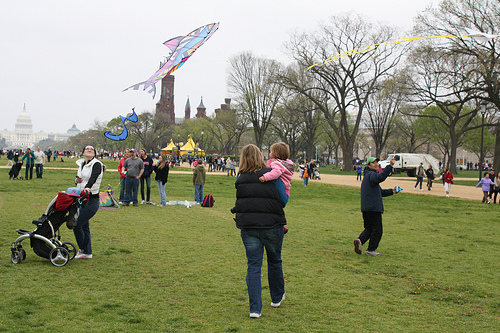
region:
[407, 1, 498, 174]
a bare tree in the park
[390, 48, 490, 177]
a bare tree in the park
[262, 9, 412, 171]
a bare tree in the park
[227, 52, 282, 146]
a bare tree in the park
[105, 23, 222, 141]
a colorful kite flying in the air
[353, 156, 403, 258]
a man wearing a dark blue jacket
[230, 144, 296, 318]
a woman wearing a black vest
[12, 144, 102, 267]
a woman wearing a white vest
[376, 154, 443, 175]
a white garbage truck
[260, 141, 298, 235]
a baby wearing a pink jacket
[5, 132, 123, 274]
a woman pushing a stroller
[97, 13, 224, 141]
a kite shaped like a fish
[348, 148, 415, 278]
a man flying a kite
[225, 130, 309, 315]
a woman carrying a baby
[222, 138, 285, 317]
a woman in ab lack coat and blue jeans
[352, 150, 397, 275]
a man in a green cap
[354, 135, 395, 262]
a man in a blue coat and black pants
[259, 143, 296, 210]
a child in a pink coat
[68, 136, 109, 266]
a woman in a white vest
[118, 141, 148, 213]
a man in a grey sweater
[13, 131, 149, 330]
a woman pushing a stroller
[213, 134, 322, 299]
a woman holding a little girl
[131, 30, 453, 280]
a man flying a kite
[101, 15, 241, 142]
a shark shaped kite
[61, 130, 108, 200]
a woman wearing a white vest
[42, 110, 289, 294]
people standing on grass in a field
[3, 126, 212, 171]
people standing on the grass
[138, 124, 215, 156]
two yellow pop up tents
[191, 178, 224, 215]
a red and black back pack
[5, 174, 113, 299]
a black stroller on the grass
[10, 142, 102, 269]
a woman with a baby stroller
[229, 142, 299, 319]
a woman carrying a baby in pink jacket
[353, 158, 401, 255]
a man flying a kite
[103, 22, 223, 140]
a blue and pink kite flying in the air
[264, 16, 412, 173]
a bare tree in the park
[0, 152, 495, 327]
green grass in the public park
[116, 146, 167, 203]
people watching kites fly in park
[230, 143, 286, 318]
a woman wearing a black vest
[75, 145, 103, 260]
a woman wearing a white vest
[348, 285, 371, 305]
Small patch of green grass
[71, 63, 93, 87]
Small patch of the white sky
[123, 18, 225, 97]
Kite in shape of a shark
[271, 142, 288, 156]
Brown hair of the toddler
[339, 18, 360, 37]
A group of branches on the tree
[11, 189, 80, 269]
Black stroller being handled by the lady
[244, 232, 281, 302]
Blue jeans of the woman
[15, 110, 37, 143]
White building in the far distance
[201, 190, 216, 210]
Red and black backpack on grass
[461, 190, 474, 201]
Brown walkway being utilized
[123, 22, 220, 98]
A kite in the air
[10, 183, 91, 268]
A baby stroller in the grass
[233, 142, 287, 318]
A woman walking in the grass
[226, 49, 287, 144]
A tree near a park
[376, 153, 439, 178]
A white truck near a park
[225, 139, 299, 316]
woman carrying small child